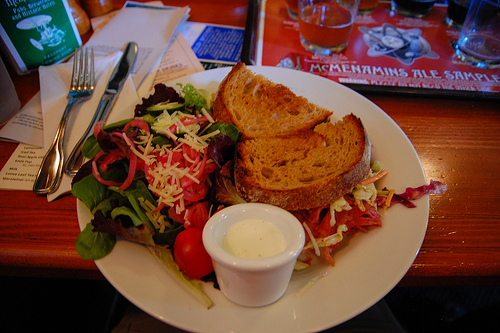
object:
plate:
[68, 60, 429, 332]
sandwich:
[233, 114, 373, 225]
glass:
[451, 0, 497, 70]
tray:
[240, 1, 499, 102]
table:
[2, 2, 498, 276]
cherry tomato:
[173, 226, 218, 280]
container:
[197, 202, 317, 309]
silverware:
[30, 41, 142, 197]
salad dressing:
[213, 216, 293, 259]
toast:
[218, 59, 334, 141]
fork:
[30, 46, 95, 195]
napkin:
[37, 50, 139, 206]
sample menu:
[254, 0, 500, 95]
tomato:
[168, 228, 218, 279]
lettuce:
[73, 218, 112, 261]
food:
[68, 62, 450, 305]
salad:
[69, 78, 235, 263]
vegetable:
[74, 222, 117, 263]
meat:
[404, 177, 450, 201]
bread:
[234, 114, 370, 213]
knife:
[60, 41, 155, 179]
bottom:
[298, 38, 349, 56]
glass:
[294, 0, 358, 24]